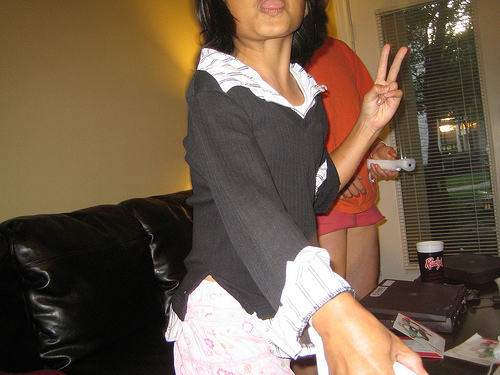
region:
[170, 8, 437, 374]
small girl giving peace sign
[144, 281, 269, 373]
white skirt on woman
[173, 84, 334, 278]
black sweater on woman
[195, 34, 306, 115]
white striped shirt under sweater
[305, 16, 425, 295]
woman playing nintendo wii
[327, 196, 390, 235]
pink shorts on woman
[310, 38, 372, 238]
orange shirt on woman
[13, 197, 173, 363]
black leather sofa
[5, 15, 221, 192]
cream colored wall behind girls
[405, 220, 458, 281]
white and black cup on table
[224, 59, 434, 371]
two people posing for a photo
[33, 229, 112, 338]
couch is black in color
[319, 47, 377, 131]
shirt is red in color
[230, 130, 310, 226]
blouse is black in color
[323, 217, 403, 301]
the person is half dressed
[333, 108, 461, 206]
person is holding a remote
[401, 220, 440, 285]
the mug is black in color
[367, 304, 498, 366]
the cards are on the table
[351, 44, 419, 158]
two fingers sticking up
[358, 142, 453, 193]
Wii remote in hand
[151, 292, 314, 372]
pink and white pants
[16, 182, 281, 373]
a black leather sofa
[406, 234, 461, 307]
a white black and red cup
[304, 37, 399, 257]
orange shirt and pink shorts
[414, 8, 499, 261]
a tree seen through window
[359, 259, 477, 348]
a laptop on the table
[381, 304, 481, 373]
a white card on table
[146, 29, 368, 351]
a gray shirt with white collar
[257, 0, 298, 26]
tongue sticking out of mouth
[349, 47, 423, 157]
fingers making peace sign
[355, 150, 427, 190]
a white Wii remote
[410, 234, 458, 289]
a black white and red cup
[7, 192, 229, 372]
a black leather sofa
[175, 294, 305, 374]
pink and white pants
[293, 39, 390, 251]
orange shirt and pink shorts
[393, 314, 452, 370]
a red and white card on table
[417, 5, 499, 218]
a tree out the window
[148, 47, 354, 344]
a gray and white shirt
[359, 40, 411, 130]
Female left hand in the air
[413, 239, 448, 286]
Coffee cup on a table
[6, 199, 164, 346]
Black leather couch next to a wall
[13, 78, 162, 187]
Beige color painted wall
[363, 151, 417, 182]
Remote game control in a hand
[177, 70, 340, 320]
Dark grey cotton sweater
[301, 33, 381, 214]
Orange long female top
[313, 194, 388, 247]
Pink very short female pants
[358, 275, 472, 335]
Closed briefcase on a table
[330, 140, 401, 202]
Female hands in the air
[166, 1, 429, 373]
dark-haired woman sticking her tongue out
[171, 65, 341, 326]
the dark gray sweater on the woman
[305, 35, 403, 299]
a woman wearing an orange t-shirt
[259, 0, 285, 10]
the woman's tongue sticking out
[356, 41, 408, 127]
the woman's left hand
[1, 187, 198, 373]
black leather couch behind the women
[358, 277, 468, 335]
a closed laptop computer on the desk